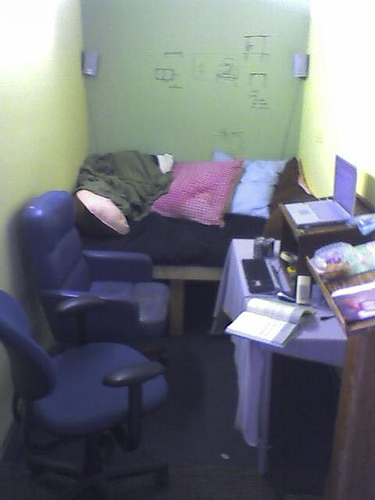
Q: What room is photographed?
A: An office.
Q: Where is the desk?
A: Against the wall.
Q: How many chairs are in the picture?
A: Two.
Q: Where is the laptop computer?
A: Top of the desk.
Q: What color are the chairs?
A: Blue.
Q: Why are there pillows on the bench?
A: To rest.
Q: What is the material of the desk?
A: Wood.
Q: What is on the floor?
A: Carpet.